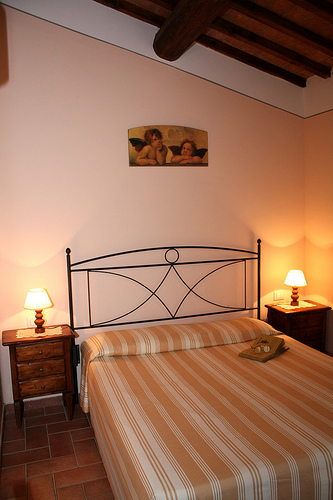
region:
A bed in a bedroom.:
[0, 0, 331, 498]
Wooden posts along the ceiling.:
[89, 0, 328, 85]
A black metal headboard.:
[64, 235, 260, 328]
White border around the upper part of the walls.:
[0, 0, 332, 119]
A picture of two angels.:
[123, 120, 203, 161]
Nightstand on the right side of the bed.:
[263, 297, 328, 343]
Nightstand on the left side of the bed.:
[0, 321, 78, 417]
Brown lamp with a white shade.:
[283, 268, 306, 305]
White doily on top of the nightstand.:
[274, 298, 316, 308]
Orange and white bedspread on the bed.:
[78, 315, 330, 496]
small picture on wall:
[124, 121, 212, 169]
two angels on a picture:
[120, 122, 220, 176]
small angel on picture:
[124, 121, 176, 165]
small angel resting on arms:
[171, 139, 204, 165]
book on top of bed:
[242, 335, 279, 359]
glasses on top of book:
[251, 343, 268, 359]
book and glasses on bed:
[230, 326, 294, 373]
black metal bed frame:
[44, 229, 269, 326]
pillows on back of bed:
[84, 326, 231, 357]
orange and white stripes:
[131, 372, 211, 431]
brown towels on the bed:
[234, 330, 298, 363]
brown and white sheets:
[144, 394, 228, 449]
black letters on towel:
[254, 333, 269, 342]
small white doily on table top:
[15, 321, 73, 338]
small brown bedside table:
[0, 322, 90, 410]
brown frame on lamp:
[31, 310, 51, 331]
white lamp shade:
[16, 284, 62, 309]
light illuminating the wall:
[13, 246, 56, 277]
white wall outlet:
[267, 285, 286, 299]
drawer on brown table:
[10, 340, 77, 373]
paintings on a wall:
[115, 115, 218, 176]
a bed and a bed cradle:
[58, 244, 331, 497]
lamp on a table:
[13, 287, 59, 343]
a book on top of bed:
[233, 331, 300, 370]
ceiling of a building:
[155, 7, 313, 90]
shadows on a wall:
[244, 215, 327, 270]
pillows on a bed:
[68, 274, 300, 364]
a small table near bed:
[5, 324, 95, 423]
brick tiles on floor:
[9, 434, 82, 497]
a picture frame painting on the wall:
[119, 119, 217, 177]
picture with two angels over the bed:
[125, 119, 216, 168]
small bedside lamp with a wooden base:
[22, 285, 54, 334]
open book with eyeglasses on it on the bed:
[237, 326, 291, 365]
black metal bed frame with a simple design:
[55, 236, 267, 328]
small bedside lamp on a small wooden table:
[277, 264, 307, 305]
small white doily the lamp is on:
[16, 324, 67, 338]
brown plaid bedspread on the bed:
[82, 335, 248, 489]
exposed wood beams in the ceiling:
[107, 0, 328, 83]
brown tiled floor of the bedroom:
[4, 435, 99, 494]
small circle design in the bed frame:
[162, 246, 181, 261]